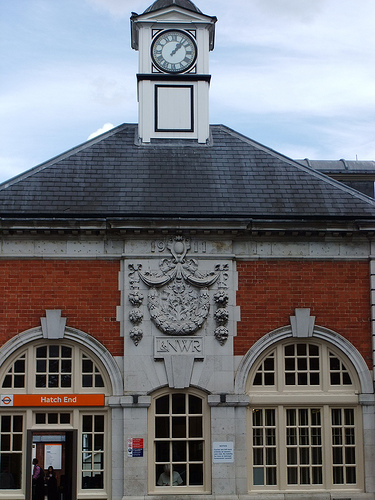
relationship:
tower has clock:
[131, 3, 215, 145] [151, 29, 200, 76]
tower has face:
[131, 3, 215, 145] [154, 30, 195, 70]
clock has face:
[151, 29, 200, 76] [154, 30, 195, 70]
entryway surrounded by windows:
[26, 428, 79, 496] [3, 337, 110, 497]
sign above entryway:
[13, 393, 105, 409] [26, 428, 79, 496]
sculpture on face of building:
[117, 238, 241, 393] [6, 4, 371, 492]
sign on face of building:
[211, 440, 236, 465] [6, 4, 371, 492]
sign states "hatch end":
[13, 393, 105, 409] [39, 394, 79, 406]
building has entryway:
[6, 4, 371, 492] [26, 428, 79, 496]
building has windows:
[6, 4, 371, 492] [3, 307, 372, 496]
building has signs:
[6, 4, 371, 492] [15, 394, 236, 475]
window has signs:
[149, 385, 213, 495] [128, 437, 237, 466]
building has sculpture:
[6, 4, 371, 492] [117, 238, 241, 393]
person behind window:
[158, 463, 185, 485] [149, 385, 213, 495]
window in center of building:
[149, 385, 213, 495] [6, 4, 371, 492]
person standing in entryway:
[32, 452, 42, 496] [26, 428, 79, 496]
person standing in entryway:
[45, 465, 56, 496] [26, 428, 79, 496]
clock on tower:
[151, 29, 200, 76] [131, 3, 215, 145]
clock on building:
[151, 29, 200, 76] [6, 4, 371, 492]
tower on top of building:
[131, 3, 215, 145] [6, 4, 371, 492]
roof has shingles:
[5, 123, 370, 219] [5, 129, 368, 208]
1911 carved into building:
[147, 235, 209, 256] [6, 4, 371, 492]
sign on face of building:
[13, 393, 105, 409] [6, 4, 371, 492]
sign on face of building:
[156, 337, 204, 358] [6, 4, 371, 492]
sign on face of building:
[126, 437, 147, 460] [6, 4, 371, 492]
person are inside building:
[32, 458, 45, 499] [6, 4, 371, 492]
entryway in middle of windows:
[26, 428, 79, 496] [3, 337, 110, 497]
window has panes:
[253, 335, 365, 495] [285, 345, 319, 355]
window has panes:
[253, 335, 365, 495] [330, 358, 342, 385]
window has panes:
[253, 335, 365, 495] [253, 410, 277, 426]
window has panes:
[253, 335, 365, 495] [289, 430, 320, 444]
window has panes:
[253, 335, 365, 495] [288, 467, 319, 483]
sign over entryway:
[13, 393, 105, 409] [26, 428, 79, 496]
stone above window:
[290, 306, 317, 339] [253, 335, 365, 495]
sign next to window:
[211, 440, 236, 465] [253, 335, 365, 495]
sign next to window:
[126, 437, 147, 460] [149, 385, 213, 495]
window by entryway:
[2, 413, 26, 452] [26, 428, 79, 496]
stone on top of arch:
[290, 306, 317, 339] [233, 326, 370, 392]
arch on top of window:
[233, 326, 370, 392] [251, 401, 366, 489]